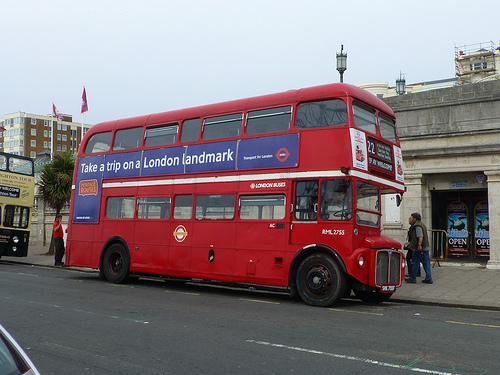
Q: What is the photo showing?
A: It is showing a road.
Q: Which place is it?
A: It is a road.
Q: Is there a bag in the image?
A: No, there are no bags.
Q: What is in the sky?
A: The clouds are in the sky.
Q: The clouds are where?
A: The clouds are in the sky.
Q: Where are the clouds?
A: The clouds are in the sky.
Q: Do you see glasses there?
A: No, there are no glasses.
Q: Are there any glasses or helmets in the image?
A: No, there are no glasses or helmets.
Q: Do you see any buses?
A: Yes, there is a bus.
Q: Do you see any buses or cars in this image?
A: Yes, there is a bus.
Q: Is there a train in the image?
A: No, there are no trains.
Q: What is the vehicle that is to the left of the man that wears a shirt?
A: The vehicle is a bus.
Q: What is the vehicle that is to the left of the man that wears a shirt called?
A: The vehicle is a bus.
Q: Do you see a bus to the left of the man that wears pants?
A: Yes, there is a bus to the left of the man.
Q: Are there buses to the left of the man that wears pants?
A: Yes, there is a bus to the left of the man.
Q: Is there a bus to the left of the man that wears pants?
A: Yes, there is a bus to the left of the man.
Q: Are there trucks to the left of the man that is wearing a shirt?
A: No, there is a bus to the left of the man.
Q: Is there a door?
A: Yes, there is a door.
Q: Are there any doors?
A: Yes, there is a door.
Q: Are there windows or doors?
A: Yes, there is a door.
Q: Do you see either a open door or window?
A: Yes, there is an open door.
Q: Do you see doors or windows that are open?
A: Yes, the door is open.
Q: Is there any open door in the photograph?
A: Yes, there is an open door.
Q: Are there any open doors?
A: Yes, there is an open door.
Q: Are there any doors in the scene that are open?
A: Yes, there is a door that is open.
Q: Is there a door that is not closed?
A: Yes, there is a open door.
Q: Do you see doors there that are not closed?
A: Yes, there is a open door.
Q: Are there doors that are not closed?
A: Yes, there is a open door.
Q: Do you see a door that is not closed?
A: Yes, there is a open door.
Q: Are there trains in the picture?
A: No, there are no trains.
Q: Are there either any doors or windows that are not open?
A: No, there is a door but it is open.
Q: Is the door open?
A: Yes, the door is open.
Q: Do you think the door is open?
A: Yes, the door is open.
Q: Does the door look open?
A: Yes, the door is open.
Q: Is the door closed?
A: No, the door is open.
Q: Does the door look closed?
A: No, the door is open.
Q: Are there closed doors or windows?
A: No, there is a door but it is open.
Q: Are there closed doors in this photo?
A: No, there is a door but it is open.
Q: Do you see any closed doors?
A: No, there is a door but it is open.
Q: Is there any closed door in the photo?
A: No, there is a door but it is open.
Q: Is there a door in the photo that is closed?
A: No, there is a door but it is open.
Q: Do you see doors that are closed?
A: No, there is a door but it is open.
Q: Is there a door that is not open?
A: No, there is a door but it is open.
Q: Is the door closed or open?
A: The door is open.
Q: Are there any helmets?
A: No, there are no helmets.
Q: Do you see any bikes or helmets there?
A: No, there are no helmets or bikes.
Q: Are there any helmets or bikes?
A: No, there are no helmets or bikes.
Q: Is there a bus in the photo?
A: Yes, there is a bus.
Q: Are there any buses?
A: Yes, there is a bus.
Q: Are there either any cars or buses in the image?
A: Yes, there is a bus.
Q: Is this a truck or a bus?
A: This is a bus.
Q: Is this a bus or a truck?
A: This is a bus.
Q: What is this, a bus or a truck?
A: This is a bus.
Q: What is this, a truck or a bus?
A: This is a bus.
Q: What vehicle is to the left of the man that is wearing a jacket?
A: The vehicle is a bus.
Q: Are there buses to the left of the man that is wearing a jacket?
A: Yes, there is a bus to the left of the man.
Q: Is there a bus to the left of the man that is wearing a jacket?
A: Yes, there is a bus to the left of the man.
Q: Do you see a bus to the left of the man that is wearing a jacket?
A: Yes, there is a bus to the left of the man.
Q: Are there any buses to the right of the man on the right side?
A: No, the bus is to the left of the man.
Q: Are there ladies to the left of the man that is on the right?
A: No, there is a bus to the left of the man.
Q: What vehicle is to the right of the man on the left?
A: The vehicle is a bus.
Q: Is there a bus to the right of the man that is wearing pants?
A: Yes, there is a bus to the right of the man.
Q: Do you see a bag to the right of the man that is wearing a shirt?
A: No, there is a bus to the right of the man.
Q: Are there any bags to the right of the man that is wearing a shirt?
A: No, there is a bus to the right of the man.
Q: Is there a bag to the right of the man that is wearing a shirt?
A: No, there is a bus to the right of the man.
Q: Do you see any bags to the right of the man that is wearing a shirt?
A: No, there is a bus to the right of the man.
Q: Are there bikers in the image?
A: No, there are no bikers.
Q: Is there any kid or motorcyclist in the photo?
A: No, there are no bikers or children.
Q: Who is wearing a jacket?
A: The man is wearing a jacket.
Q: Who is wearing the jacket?
A: The man is wearing a jacket.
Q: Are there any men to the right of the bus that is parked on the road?
A: Yes, there is a man to the right of the bus.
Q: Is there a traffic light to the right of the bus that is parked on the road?
A: No, there is a man to the right of the bus.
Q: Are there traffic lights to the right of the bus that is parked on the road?
A: No, there is a man to the right of the bus.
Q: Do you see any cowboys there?
A: No, there are no cowboys.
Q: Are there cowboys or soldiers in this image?
A: No, there are no cowboys or soldiers.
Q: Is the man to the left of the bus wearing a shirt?
A: Yes, the man is wearing a shirt.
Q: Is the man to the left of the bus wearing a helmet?
A: No, the man is wearing a shirt.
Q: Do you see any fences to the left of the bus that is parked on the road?
A: No, there is a man to the left of the bus.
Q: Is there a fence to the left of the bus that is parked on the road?
A: No, there is a man to the left of the bus.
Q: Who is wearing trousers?
A: The man is wearing trousers.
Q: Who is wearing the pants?
A: The man is wearing trousers.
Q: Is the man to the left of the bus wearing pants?
A: Yes, the man is wearing pants.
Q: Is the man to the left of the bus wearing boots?
A: No, the man is wearing pants.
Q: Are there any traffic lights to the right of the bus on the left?
A: No, there is a man to the right of the bus.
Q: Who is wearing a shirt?
A: The man is wearing a shirt.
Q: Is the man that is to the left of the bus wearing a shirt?
A: Yes, the man is wearing a shirt.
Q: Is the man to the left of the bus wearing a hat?
A: No, the man is wearing a shirt.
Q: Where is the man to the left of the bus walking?
A: The man is walking on the sidewalk.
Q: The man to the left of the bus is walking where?
A: The man is walking on the sidewalk.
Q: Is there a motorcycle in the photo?
A: No, there are no motorcycles.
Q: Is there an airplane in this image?
A: No, there are no airplanes.